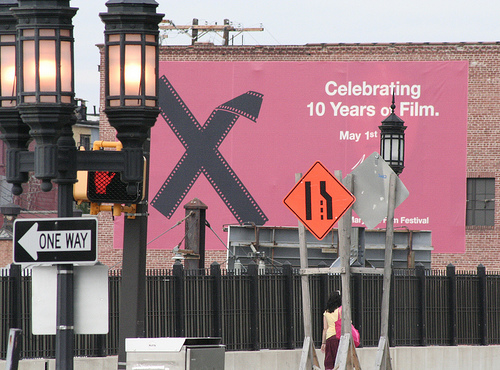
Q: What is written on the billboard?
A: Celebrating 10 years of film.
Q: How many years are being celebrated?
A: Ten.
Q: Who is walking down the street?
A: A lady.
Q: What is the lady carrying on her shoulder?
A: A bag.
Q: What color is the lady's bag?
A: Pink.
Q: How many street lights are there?
A: Four.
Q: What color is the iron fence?
A: Black.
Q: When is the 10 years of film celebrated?
A: On May 1st.